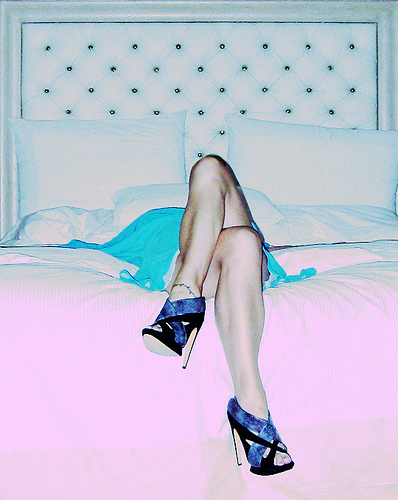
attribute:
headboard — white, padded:
[0, 0, 397, 244]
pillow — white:
[10, 115, 190, 231]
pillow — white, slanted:
[227, 114, 397, 221]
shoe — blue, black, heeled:
[140, 293, 206, 370]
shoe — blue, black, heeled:
[227, 395, 295, 476]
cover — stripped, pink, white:
[0, 209, 395, 500]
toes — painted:
[272, 447, 293, 466]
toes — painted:
[144, 319, 162, 332]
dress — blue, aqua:
[61, 206, 318, 289]